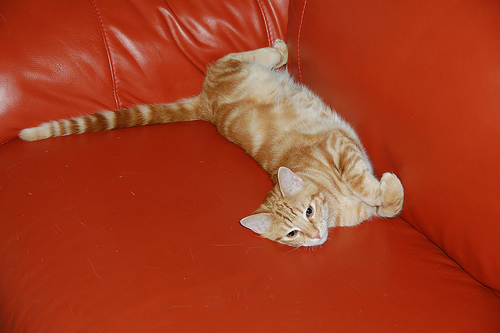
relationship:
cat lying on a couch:
[19, 39, 406, 248] [0, 0, 500, 333]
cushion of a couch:
[2, 119, 484, 331] [0, 0, 500, 333]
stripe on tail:
[43, 121, 59, 141] [18, 89, 201, 146]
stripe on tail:
[51, 113, 69, 139] [18, 96, 200, 142]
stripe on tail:
[68, 116, 81, 137] [18, 89, 201, 146]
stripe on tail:
[80, 105, 96, 136] [18, 89, 201, 146]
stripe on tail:
[90, 109, 107, 132] [17, 82, 202, 143]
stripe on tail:
[102, 107, 125, 131] [18, 89, 201, 146]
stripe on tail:
[116, 103, 132, 127] [18, 89, 201, 146]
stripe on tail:
[140, 104, 162, 125] [18, 89, 201, 146]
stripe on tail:
[158, 100, 172, 124] [18, 89, 201, 146]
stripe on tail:
[170, 95, 190, 125] [18, 89, 201, 146]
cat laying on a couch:
[19, 39, 406, 248] [5, 11, 497, 309]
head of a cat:
[238, 166, 328, 249] [158, 39, 414, 279]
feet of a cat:
[201, 33, 311, 100] [225, 82, 405, 287]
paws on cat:
[354, 166, 426, 242] [208, 130, 420, 288]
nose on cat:
[301, 220, 328, 250] [232, 164, 370, 273]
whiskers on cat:
[281, 235, 308, 260] [245, 150, 359, 275]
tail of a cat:
[18, 96, 200, 142] [185, 40, 425, 292]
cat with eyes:
[274, 197, 328, 249] [279, 199, 313, 239]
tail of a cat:
[28, 88, 215, 151] [188, 50, 435, 277]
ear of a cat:
[272, 155, 315, 205] [203, 111, 419, 283]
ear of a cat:
[228, 199, 286, 257] [216, 144, 366, 269]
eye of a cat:
[284, 230, 298, 238] [201, 151, 350, 263]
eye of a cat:
[270, 222, 308, 249] [212, 124, 384, 282]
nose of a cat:
[301, 221, 321, 239] [219, 131, 382, 309]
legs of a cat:
[352, 173, 419, 242] [221, 135, 368, 284]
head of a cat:
[208, 151, 348, 287] [192, 60, 417, 278]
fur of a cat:
[241, 88, 306, 173] [172, 31, 461, 329]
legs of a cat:
[232, 33, 301, 82] [192, 60, 417, 278]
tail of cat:
[18, 96, 200, 142] [19, 39, 406, 248]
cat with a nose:
[19, 39, 406, 248] [306, 228, 324, 246]